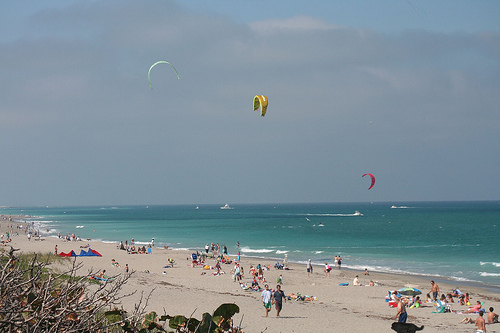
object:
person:
[460, 317, 475, 324]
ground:
[0, 285, 499, 329]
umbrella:
[397, 287, 421, 295]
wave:
[306, 214, 353, 217]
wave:
[480, 262, 485, 265]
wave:
[480, 272, 500, 276]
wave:
[241, 247, 273, 253]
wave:
[76, 226, 83, 229]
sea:
[2, 202, 499, 289]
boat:
[220, 203, 232, 209]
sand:
[122, 275, 405, 321]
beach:
[3, 213, 500, 330]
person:
[272, 285, 286, 316]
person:
[261, 284, 272, 317]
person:
[394, 299, 406, 322]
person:
[353, 275, 362, 285]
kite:
[362, 173, 376, 190]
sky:
[0, 1, 495, 208]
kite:
[253, 95, 268, 117]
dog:
[391, 322, 424, 331]